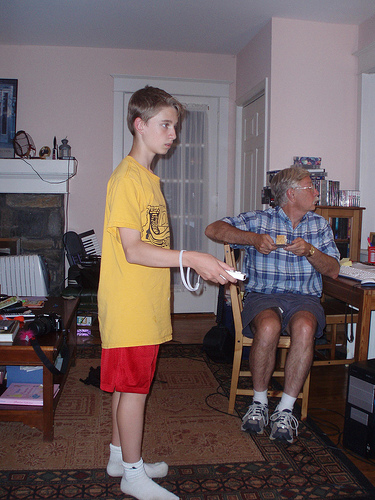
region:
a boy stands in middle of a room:
[89, 82, 245, 498]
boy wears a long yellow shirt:
[89, 84, 250, 497]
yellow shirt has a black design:
[89, 157, 179, 349]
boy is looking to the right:
[82, 83, 250, 497]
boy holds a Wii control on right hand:
[94, 86, 254, 296]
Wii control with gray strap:
[173, 239, 251, 296]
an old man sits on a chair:
[201, 164, 350, 450]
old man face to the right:
[202, 159, 350, 450]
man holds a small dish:
[194, 159, 352, 293]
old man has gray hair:
[227, 160, 350, 256]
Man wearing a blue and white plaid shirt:
[220, 165, 341, 298]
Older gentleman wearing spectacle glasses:
[268, 166, 322, 215]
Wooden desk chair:
[222, 243, 312, 424]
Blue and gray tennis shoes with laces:
[238, 399, 300, 447]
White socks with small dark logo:
[105, 441, 181, 498]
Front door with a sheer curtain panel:
[106, 69, 230, 314]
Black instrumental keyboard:
[61, 228, 101, 268]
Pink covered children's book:
[0, 381, 61, 407]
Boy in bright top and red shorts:
[95, 87, 183, 395]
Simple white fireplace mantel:
[0, 155, 78, 196]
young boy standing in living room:
[96, 81, 234, 496]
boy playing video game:
[99, 84, 245, 494]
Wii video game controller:
[177, 249, 247, 292]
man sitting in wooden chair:
[204, 165, 339, 443]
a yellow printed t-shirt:
[96, 156, 175, 347]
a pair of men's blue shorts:
[240, 291, 327, 338]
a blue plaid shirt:
[226, 205, 339, 294]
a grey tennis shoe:
[242, 399, 269, 434]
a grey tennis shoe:
[268, 405, 298, 443]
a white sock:
[118, 459, 180, 499]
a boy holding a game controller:
[105, 78, 255, 291]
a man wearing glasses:
[273, 170, 321, 223]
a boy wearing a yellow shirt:
[100, 117, 186, 362]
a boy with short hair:
[122, 82, 185, 169]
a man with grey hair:
[257, 168, 318, 219]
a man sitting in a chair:
[230, 173, 333, 396]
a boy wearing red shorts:
[88, 89, 181, 496]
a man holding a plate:
[271, 156, 363, 327]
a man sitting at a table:
[252, 156, 350, 323]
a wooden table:
[0, 290, 83, 473]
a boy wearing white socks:
[101, 464, 195, 498]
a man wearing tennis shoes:
[252, 371, 312, 462]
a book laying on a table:
[8, 373, 64, 419]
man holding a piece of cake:
[263, 213, 308, 269]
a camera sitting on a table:
[25, 303, 71, 346]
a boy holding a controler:
[195, 242, 260, 306]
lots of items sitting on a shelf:
[8, 123, 91, 170]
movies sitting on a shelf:
[321, 170, 366, 226]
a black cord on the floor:
[197, 376, 247, 423]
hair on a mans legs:
[251, 326, 296, 398]